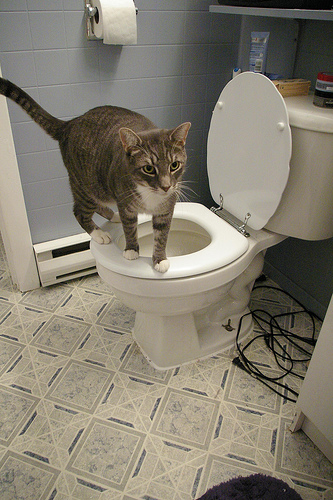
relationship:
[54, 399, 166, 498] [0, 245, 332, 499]
tile on floor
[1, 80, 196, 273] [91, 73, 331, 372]
cat on toilet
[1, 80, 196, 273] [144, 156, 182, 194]
cat has face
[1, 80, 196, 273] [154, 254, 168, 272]
cat has paw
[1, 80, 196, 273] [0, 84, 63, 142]
cat has tail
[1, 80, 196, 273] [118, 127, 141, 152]
cat has ear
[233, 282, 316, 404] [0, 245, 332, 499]
wire on floor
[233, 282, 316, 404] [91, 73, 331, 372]
wire behind toilet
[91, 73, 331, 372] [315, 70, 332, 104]
toilet has bottle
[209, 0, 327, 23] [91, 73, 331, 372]
shelf above toilet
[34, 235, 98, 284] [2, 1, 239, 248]
vent on wall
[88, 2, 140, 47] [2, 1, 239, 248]
toilet paper on wall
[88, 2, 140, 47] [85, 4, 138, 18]
toilet paper on holder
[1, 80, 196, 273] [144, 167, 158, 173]
cat has eye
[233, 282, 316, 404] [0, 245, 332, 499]
cord on floor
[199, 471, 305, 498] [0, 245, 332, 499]
rug on floor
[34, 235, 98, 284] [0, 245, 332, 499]
heating register on floor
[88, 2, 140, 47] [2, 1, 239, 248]
dispenser on wall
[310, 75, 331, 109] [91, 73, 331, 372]
toiletry on toilet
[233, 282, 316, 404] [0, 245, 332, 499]
cable on floor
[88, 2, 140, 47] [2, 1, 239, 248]
napkin roll on wall